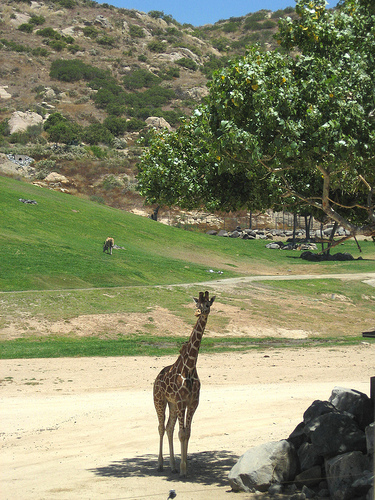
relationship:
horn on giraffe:
[205, 290, 210, 301] [153, 288, 217, 477]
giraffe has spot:
[151, 288, 224, 456] [178, 336, 192, 355]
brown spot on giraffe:
[193, 324, 202, 333] [146, 288, 221, 478]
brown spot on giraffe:
[173, 379, 179, 384] [146, 288, 221, 478]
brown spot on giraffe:
[176, 377, 180, 383] [101, 278, 257, 485]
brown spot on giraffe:
[181, 364, 193, 379] [146, 288, 221, 478]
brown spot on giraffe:
[189, 348, 195, 359] [90, 274, 231, 470]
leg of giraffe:
[151, 395, 167, 476] [146, 288, 221, 478]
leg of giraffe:
[163, 409, 177, 477] [153, 288, 217, 477]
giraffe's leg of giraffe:
[175, 411, 187, 481] [153, 288, 217, 477]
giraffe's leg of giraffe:
[182, 405, 199, 441] [153, 288, 217, 477]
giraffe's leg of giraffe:
[164, 411, 180, 474] [153, 288, 217, 477]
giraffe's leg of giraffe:
[154, 412, 167, 473] [153, 288, 217, 477]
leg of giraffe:
[153, 395, 167, 471] [146, 288, 221, 478]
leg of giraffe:
[166, 411, 178, 473] [146, 288, 221, 478]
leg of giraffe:
[176, 406, 187, 479] [146, 288, 221, 478]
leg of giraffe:
[186, 404, 201, 460] [146, 288, 221, 478]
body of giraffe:
[152, 365, 205, 414] [153, 288, 217, 477]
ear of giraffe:
[185, 293, 199, 305] [138, 281, 217, 480]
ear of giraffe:
[210, 296, 217, 306] [138, 281, 217, 480]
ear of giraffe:
[206, 292, 218, 304] [104, 269, 278, 475]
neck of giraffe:
[192, 323, 202, 341] [153, 278, 198, 474]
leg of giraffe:
[173, 400, 189, 479] [153, 288, 217, 477]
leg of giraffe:
[186, 404, 201, 460] [153, 288, 217, 477]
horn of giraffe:
[195, 289, 205, 302] [162, 288, 240, 366]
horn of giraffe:
[204, 291, 209, 301] [153, 288, 217, 477]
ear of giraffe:
[193, 297, 198, 302] [152, 291, 204, 479]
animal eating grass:
[97, 233, 118, 257] [0, 165, 370, 334]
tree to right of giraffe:
[141, 0, 374, 235] [153, 288, 217, 477]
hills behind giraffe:
[1, 2, 367, 231] [146, 288, 221, 478]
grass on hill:
[29, 184, 219, 291] [1, 173, 369, 343]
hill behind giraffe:
[1, 173, 369, 343] [133, 285, 289, 454]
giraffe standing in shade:
[153, 288, 217, 477] [86, 448, 240, 485]